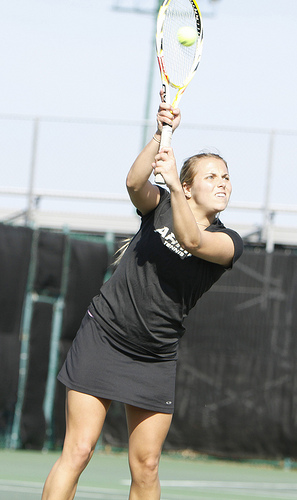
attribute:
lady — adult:
[40, 88, 244, 499]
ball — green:
[180, 28, 196, 49]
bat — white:
[153, 1, 206, 183]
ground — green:
[1, 448, 296, 499]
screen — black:
[0, 226, 297, 461]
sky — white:
[0, 0, 297, 243]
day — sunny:
[0, 0, 297, 499]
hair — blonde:
[110, 152, 228, 270]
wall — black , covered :
[11, 220, 294, 452]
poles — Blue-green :
[15, 223, 119, 453]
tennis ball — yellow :
[173, 21, 198, 50]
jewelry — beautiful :
[150, 133, 162, 147]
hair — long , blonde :
[112, 147, 233, 267]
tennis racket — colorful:
[149, 2, 205, 184]